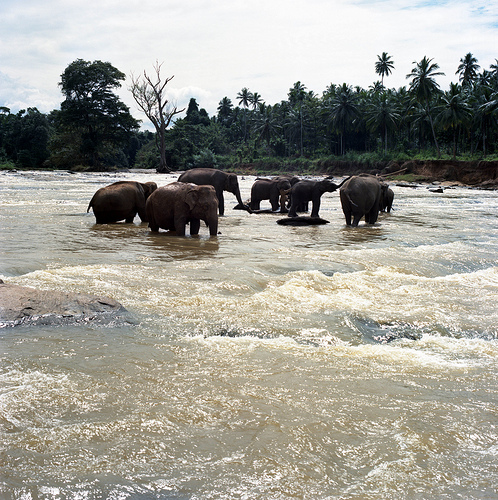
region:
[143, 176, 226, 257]
Large animal in the water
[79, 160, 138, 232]
Large animal in the water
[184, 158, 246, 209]
Large animal in the water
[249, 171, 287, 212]
Large animal in the water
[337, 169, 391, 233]
Large animal in the water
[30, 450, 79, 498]
Small ripples in the water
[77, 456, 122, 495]
Small ripples in the water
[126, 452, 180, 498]
Small ripples in the water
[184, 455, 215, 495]
Small ripples in the water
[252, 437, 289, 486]
Small ripples in the water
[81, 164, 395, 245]
elephants in a river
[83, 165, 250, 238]
three elephants in a river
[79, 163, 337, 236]
five elephants in a river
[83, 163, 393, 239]
six elephants in a river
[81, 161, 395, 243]
group of elephants bathing in a river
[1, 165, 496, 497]
elephants in foamy brown river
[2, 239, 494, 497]
brown foamy river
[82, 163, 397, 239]
small group of elephants in a river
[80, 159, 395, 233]
elephants in brownish water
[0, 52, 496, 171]
plenty of plants and trees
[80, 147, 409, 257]
elephants in the water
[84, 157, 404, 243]
a small herd of elephants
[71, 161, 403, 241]
elephants taking a bath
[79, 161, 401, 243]
elephants getting a drink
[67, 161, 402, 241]
elephants cooling off in the water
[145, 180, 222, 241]
an elephant standing in water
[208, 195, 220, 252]
an elephant trunk in water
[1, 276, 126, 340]
a rock in the water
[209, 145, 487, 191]
a riverbank in the distance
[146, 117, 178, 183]
a tree in the water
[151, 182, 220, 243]
elephant in a river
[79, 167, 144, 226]
elephant in a river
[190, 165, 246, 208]
elephant in a river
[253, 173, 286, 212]
elephant in a river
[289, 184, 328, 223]
elephant in a river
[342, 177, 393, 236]
elephant in a river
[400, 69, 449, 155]
palm tree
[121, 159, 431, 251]
herd of elephants in the water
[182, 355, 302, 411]
murky body of water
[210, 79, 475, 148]
trees along the horizon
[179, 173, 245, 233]
the head of a elephant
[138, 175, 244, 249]
a elephant in the river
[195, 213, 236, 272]
the trunk of a elephant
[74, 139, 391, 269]
lots of elephant in the water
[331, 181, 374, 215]
the tail of a elephant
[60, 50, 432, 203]
a heavily wooded area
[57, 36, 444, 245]
trees near a river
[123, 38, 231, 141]
a tree with no leaves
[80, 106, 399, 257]
a river with elephants in it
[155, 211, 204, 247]
the legs on a elephant